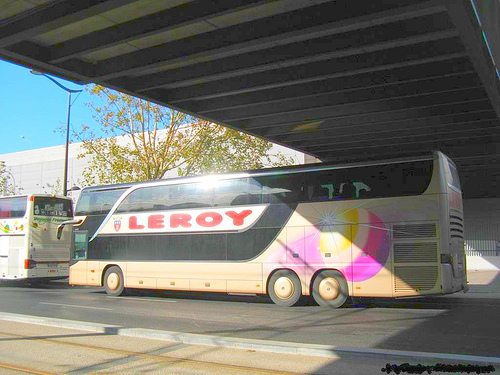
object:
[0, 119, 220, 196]
building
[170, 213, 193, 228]
letter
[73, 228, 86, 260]
door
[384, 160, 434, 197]
window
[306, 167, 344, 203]
window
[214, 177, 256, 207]
window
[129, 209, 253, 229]
logo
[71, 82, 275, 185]
branches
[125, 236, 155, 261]
bottom window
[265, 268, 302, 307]
tire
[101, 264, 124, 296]
tire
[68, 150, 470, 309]
bus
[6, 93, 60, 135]
sky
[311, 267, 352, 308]
tire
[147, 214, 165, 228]
letter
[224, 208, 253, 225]
letter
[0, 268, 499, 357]
street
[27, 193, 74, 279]
back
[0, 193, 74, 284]
decker bus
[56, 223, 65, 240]
mirror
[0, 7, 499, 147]
freeway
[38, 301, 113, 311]
line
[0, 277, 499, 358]
freeway